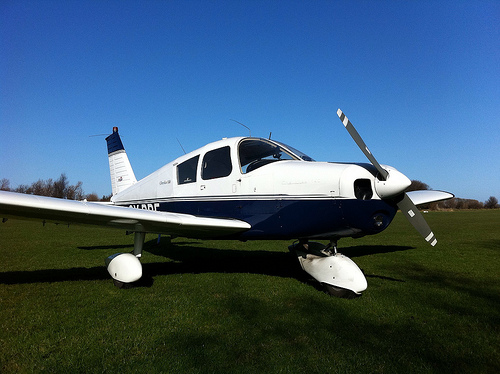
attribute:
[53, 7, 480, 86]
sky — clear, blue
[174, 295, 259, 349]
grass — green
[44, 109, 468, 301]
airplane — blue, white, large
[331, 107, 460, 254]
propeller — gray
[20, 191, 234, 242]
wing — white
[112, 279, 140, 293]
wheel — black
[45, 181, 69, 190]
leaves — green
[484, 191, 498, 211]
tree — brown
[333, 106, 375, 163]
propeller blade — white, black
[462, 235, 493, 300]
field — grassy, green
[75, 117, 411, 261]
plane — black, white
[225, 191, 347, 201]
stripes — white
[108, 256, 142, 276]
covers — white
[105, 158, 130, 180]
rear tail — white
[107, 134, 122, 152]
rear tail — blue